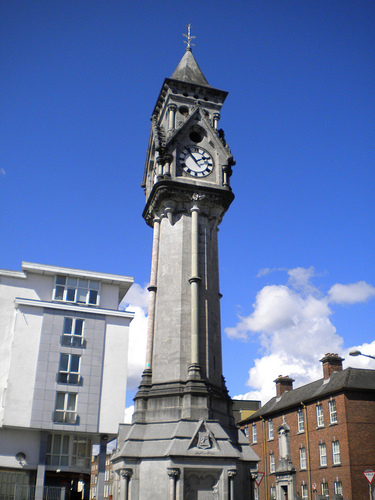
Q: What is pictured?
A: Clock tower.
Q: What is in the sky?
A: Clouds.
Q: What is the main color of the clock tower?
A: Gray.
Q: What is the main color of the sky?
A: Blue.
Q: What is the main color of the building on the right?
A: Brown.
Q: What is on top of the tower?
A: Clock.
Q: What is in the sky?
A: Clouds.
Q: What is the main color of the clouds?
A: White.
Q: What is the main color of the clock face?
A: White.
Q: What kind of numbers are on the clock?
A: Roman numerals.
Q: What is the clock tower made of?
A: Stone.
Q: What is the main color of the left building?
A: Gray.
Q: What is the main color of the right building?
A: Brown.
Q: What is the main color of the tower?
A: Gray.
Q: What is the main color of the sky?
A: Blue.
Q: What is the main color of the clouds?
A: White.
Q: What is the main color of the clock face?
A: White.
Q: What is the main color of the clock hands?
A: Black.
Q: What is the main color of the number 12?
A: Black.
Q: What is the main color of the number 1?
A: Black.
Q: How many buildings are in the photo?
A: Two.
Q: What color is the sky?
A: Blue.